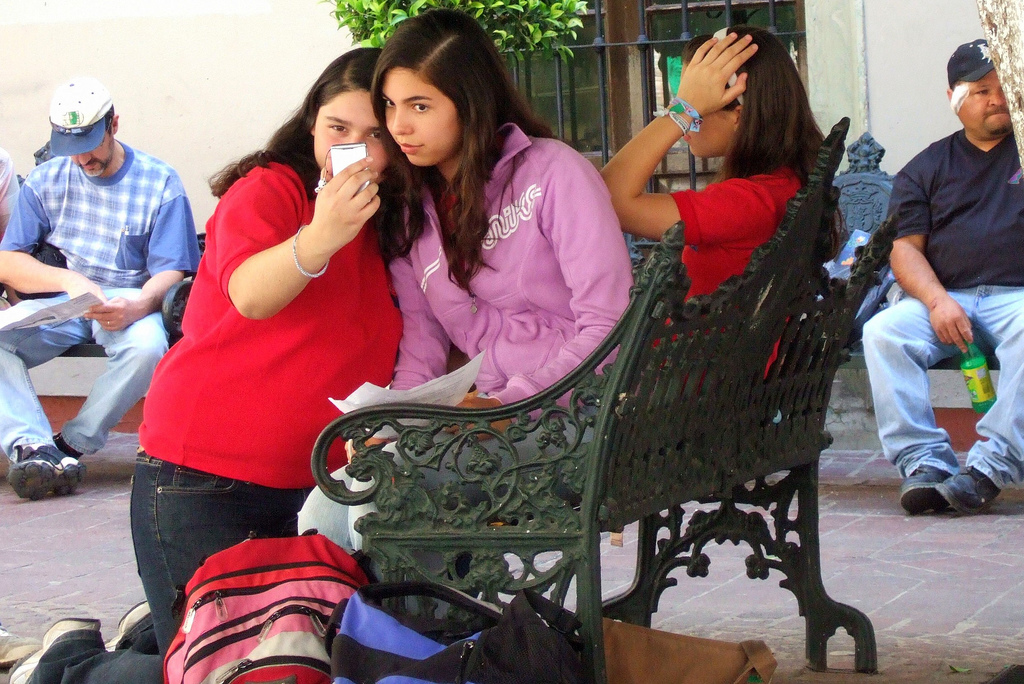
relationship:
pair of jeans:
[1, 294, 172, 457] [7, 305, 174, 452]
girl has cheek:
[296, 10, 632, 551] [423, 118, 452, 149]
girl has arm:
[10, 47, 397, 680] [181, 186, 333, 320]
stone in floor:
[874, 574, 1006, 639] [0, 430, 1018, 677]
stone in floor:
[859, 520, 1015, 581] [0, 430, 1018, 677]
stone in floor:
[676, 555, 798, 646] [0, 430, 1018, 677]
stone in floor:
[6, 522, 99, 575] [0, 430, 1018, 677]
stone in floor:
[829, 464, 901, 508] [0, 430, 1018, 677]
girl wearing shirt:
[9, 47, 404, 679] [138, 162, 400, 489]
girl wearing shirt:
[289, 0, 630, 573] [386, 121, 631, 422]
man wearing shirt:
[864, 41, 1022, 512] [888, 131, 1016, 287]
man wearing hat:
[864, 41, 1022, 512] [948, 37, 994, 85]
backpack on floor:
[166, 531, 370, 681] [0, 420, 1017, 678]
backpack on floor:
[330, 579, 583, 681] [0, 420, 1017, 678]